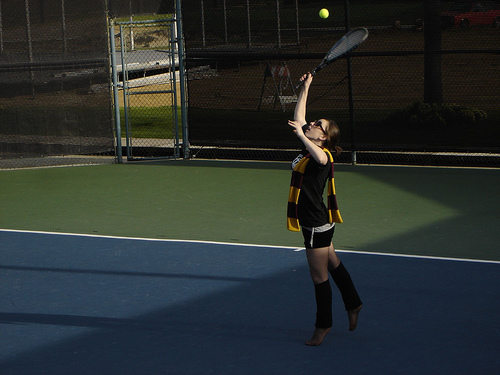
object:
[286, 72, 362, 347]
woman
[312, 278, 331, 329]
leg warmer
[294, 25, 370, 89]
racquet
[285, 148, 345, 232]
scarf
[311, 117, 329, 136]
sunglasses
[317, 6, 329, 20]
tennis ball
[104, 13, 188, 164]
gate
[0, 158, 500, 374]
tennis court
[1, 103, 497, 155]
grass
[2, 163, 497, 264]
outside court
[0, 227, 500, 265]
line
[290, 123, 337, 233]
shirt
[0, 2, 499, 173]
fence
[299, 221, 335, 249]
shorts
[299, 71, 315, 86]
hand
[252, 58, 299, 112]
traffic sawhorse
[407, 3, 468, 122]
tree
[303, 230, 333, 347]
leg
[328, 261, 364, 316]
leg warmer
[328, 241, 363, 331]
leg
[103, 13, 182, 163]
entrance